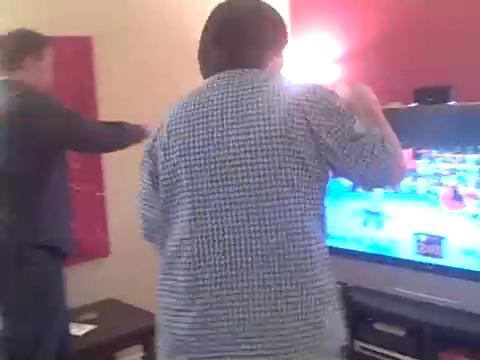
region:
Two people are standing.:
[7, 33, 460, 339]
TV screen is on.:
[327, 132, 479, 297]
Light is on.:
[279, 20, 367, 68]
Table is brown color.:
[71, 286, 163, 342]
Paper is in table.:
[69, 292, 106, 348]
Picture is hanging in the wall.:
[48, 12, 125, 122]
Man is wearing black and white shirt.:
[162, 112, 348, 341]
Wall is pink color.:
[280, 0, 473, 77]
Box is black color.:
[412, 79, 457, 108]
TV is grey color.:
[321, 108, 477, 294]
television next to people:
[361, 130, 467, 245]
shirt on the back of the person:
[187, 127, 312, 238]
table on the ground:
[88, 287, 146, 350]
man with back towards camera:
[162, 11, 347, 217]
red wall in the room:
[370, 15, 439, 71]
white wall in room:
[114, 12, 187, 62]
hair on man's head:
[178, 6, 291, 99]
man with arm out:
[16, 27, 148, 196]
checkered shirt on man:
[182, 91, 322, 235]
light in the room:
[285, 14, 363, 85]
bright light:
[276, 9, 370, 123]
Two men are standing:
[0, 21, 418, 359]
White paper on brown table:
[68, 316, 103, 342]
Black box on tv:
[412, 75, 454, 108]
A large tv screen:
[315, 96, 478, 277]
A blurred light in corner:
[281, 28, 357, 104]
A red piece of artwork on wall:
[1, 27, 127, 261]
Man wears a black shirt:
[4, 75, 151, 259]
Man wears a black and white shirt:
[121, 60, 428, 359]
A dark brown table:
[70, 296, 168, 358]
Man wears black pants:
[3, 240, 107, 359]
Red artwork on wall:
[44, 26, 110, 263]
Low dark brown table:
[58, 291, 166, 359]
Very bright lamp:
[277, 32, 346, 90]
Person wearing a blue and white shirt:
[131, 4, 371, 356]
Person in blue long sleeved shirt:
[0, 35, 148, 254]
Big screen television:
[310, 102, 478, 312]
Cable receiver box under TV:
[348, 316, 420, 359]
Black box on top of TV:
[413, 82, 456, 107]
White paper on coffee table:
[64, 315, 99, 341]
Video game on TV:
[316, 110, 479, 277]